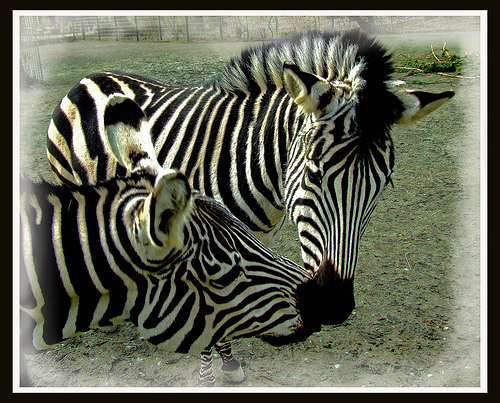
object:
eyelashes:
[389, 176, 394, 187]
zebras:
[15, 92, 321, 386]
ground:
[385, 180, 451, 359]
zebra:
[46, 29, 457, 387]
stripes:
[326, 162, 345, 272]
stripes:
[236, 93, 283, 228]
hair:
[198, 28, 396, 142]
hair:
[20, 172, 155, 191]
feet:
[221, 360, 245, 384]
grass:
[389, 45, 469, 84]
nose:
[317, 291, 355, 317]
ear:
[147, 169, 192, 248]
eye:
[234, 254, 242, 264]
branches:
[394, 41, 480, 79]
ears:
[282, 60, 336, 113]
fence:
[20, 16, 481, 86]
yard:
[20, 15, 481, 388]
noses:
[301, 320, 322, 340]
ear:
[397, 90, 456, 124]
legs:
[198, 348, 218, 386]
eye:
[307, 168, 321, 181]